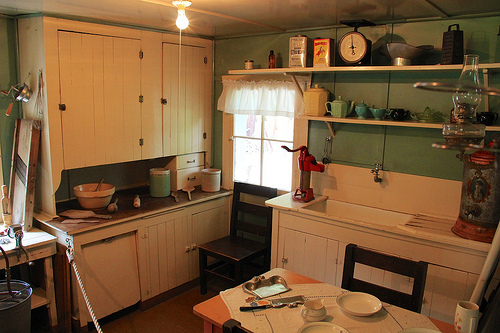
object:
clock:
[338, 30, 371, 62]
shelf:
[227, 62, 497, 76]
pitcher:
[295, 294, 334, 326]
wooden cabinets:
[36, 18, 258, 160]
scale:
[334, 16, 374, 64]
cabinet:
[16, 14, 213, 171]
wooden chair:
[191, 177, 271, 302]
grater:
[438, 21, 467, 72]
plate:
[335, 290, 382, 316]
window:
[203, 75, 308, 220]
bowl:
[73, 171, 100, 207]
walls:
[322, 63, 492, 165]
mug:
[446, 290, 484, 331]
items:
[285, 33, 392, 72]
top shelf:
[222, 63, 418, 73]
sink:
[256, 155, 494, 328]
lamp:
[434, 43, 497, 160]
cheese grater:
[440, 21, 465, 63]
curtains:
[209, 81, 307, 198]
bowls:
[287, 278, 393, 330]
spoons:
[171, 185, 195, 205]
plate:
[291, 317, 347, 331]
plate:
[398, 327, 445, 331]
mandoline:
[3, 111, 67, 246]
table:
[193, 267, 458, 332]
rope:
[58, 241, 113, 331]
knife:
[236, 295, 296, 312]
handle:
[238, 302, 268, 311]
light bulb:
[174, 7, 191, 29]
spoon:
[88, 180, 105, 196]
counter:
[45, 179, 234, 236]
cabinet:
[66, 228, 142, 329]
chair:
[187, 179, 279, 303]